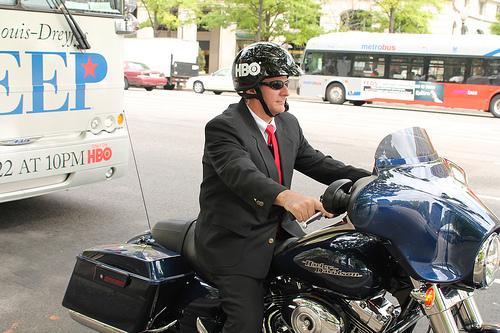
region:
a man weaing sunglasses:
[265, 72, 296, 99]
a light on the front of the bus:
[101, 160, 119, 183]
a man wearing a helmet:
[225, 47, 300, 99]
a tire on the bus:
[329, 69, 346, 116]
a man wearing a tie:
[259, 114, 295, 181]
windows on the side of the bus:
[344, 52, 390, 92]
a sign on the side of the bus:
[360, 72, 399, 104]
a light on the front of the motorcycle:
[459, 222, 499, 292]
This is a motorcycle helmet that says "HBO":
[245, 37, 282, 91]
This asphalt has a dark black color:
[19, 240, 24, 256]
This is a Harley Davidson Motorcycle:
[316, 235, 370, 292]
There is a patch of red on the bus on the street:
[448, 81, 474, 113]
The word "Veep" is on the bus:
[6, 53, 108, 106]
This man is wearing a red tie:
[264, 123, 280, 183]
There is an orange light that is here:
[423, 283, 438, 305]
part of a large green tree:
[132, 0, 321, 49]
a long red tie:
[262, 121, 284, 186]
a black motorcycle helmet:
[224, 41, 300, 116]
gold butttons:
[249, 195, 264, 208]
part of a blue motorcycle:
[149, 104, 499, 331]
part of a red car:
[125, 60, 171, 92]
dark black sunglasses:
[257, 77, 291, 92]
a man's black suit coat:
[195, 95, 367, 292]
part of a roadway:
[293, 93, 498, 206]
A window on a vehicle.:
[303, 48, 320, 73]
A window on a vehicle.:
[353, 51, 383, 76]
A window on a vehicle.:
[388, 55, 409, 77]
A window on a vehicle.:
[408, 57, 425, 80]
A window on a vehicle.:
[431, 60, 463, 82]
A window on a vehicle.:
[469, 61, 499, 84]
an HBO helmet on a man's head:
[231, 42, 303, 119]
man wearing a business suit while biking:
[197, 39, 373, 331]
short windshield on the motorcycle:
[372, 125, 436, 174]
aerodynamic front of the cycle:
[351, 159, 493, 284]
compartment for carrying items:
[59, 239, 183, 331]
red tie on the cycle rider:
[265, 123, 281, 181]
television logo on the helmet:
[230, 60, 266, 79]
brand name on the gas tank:
[297, 256, 366, 281]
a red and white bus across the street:
[297, 35, 499, 115]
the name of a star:
[0, 22, 92, 49]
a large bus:
[293, 32, 493, 106]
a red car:
[120, 56, 164, 87]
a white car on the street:
[187, 67, 249, 87]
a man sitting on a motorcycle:
[81, 47, 474, 332]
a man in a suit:
[201, 39, 325, 321]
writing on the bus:
[361, 41, 396, 52]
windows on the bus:
[308, 53, 498, 85]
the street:
[111, 85, 493, 198]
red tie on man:
[256, 123, 290, 191]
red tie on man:
[262, 119, 287, 184]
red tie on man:
[256, 118, 290, 190]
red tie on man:
[256, 122, 298, 189]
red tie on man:
[255, 120, 290, 182]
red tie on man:
[253, 120, 285, 185]